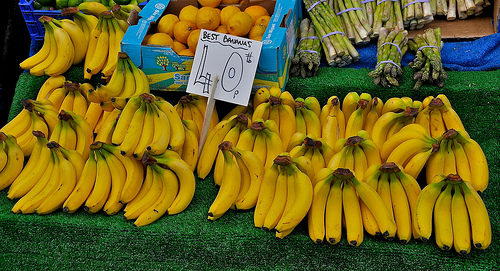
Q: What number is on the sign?
A: 40.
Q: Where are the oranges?
A: Behind the sign.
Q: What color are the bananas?
A: Yellow.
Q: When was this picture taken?
A: Daytime.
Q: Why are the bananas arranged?
A: To be sold.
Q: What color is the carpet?
A: Green.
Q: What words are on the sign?
A: Best bananas.